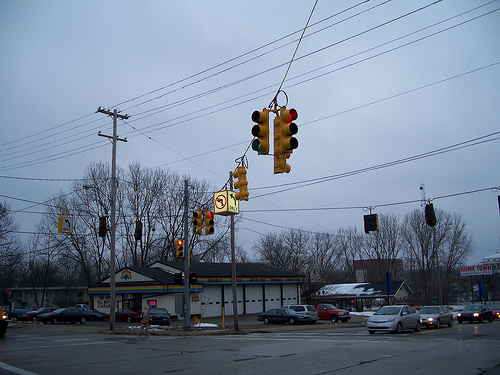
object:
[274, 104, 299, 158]
traffic light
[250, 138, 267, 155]
light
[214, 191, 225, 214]
sign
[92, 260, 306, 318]
building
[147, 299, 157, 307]
sign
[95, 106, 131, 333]
pole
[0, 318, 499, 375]
road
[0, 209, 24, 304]
trees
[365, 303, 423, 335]
car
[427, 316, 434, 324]
headlight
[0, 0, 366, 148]
wire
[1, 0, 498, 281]
sky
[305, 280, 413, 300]
roof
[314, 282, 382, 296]
snow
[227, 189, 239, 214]
sign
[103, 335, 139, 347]
puddle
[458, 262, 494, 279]
sign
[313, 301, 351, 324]
truck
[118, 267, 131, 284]
logo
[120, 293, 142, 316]
door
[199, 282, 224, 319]
garage door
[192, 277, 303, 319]
garage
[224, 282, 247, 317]
door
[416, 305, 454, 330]
car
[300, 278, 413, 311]
building